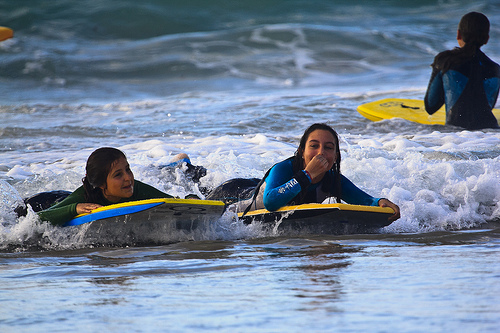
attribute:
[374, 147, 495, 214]
ripples — white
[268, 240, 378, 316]
reflection — Faint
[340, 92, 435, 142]
surfboard — yellow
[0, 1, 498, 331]
water — splashy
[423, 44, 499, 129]
costume — black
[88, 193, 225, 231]
surfboard — yellow, blue